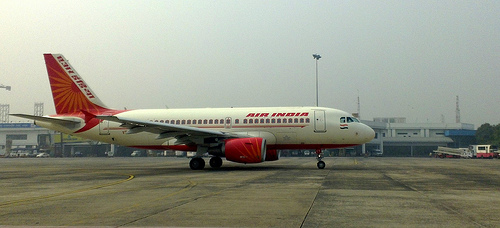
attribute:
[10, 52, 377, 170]
plane — white, stationary, parked, red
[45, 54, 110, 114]
tail — red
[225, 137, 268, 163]
engine — red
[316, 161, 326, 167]
wheel — black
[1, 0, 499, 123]
sky — overcast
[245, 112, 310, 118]
lettering — red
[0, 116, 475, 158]
building — short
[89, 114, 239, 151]
wing — grey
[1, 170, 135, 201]
line — yellow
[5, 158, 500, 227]
ground — cement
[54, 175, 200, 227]
line — yellow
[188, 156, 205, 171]
wheel — black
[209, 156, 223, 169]
wheel — black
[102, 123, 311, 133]
line — red, long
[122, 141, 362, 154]
underside — red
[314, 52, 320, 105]
pole — tall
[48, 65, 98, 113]
design — yellow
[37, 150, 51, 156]
vehicle — parked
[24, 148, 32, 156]
vehicle — parked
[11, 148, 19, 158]
vehicle — parked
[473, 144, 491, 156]
vehicle — parked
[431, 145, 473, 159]
vehicle — parked